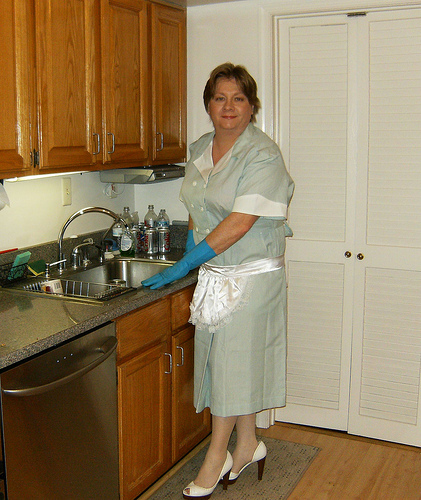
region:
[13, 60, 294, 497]
A woman standing next to a sink.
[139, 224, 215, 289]
Blue gloves on the woman's hands.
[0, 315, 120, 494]
Stainless steel dishwasher.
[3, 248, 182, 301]
A stainless steel sink.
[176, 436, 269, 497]
White shoes with brown heels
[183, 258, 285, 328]
White apron with a ruffle trim.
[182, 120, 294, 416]
Woman is wearing a blue and white dress.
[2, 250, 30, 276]
Green sponge on the edge of the sink.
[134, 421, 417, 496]
Brown wood flooring.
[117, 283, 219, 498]
Brown cupboards below the sink.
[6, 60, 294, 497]
a person in the kitchen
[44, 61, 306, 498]
a person in front of the sink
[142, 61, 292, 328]
a person wearing a blue gloves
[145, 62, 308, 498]
a person wearing high heels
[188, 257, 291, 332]
an apron the person is wearing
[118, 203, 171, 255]
bottles and soda cans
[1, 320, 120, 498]
a dishwasher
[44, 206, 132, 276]
a faucet on the sink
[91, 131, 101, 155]
a cabinet handle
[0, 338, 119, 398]
a handle of the dishwasher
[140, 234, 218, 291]
a blue glove on a woman's hand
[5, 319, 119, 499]
a metal dishwasher door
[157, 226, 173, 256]
a Diet Coke can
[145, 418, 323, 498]
a rug on the floor in front of a sink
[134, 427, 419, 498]
a light brown wood floor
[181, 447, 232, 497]
a white high heeled shoe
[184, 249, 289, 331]
a smal white apron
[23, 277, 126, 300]
a dish drainer in the sink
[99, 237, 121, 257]
a blue handled scrub brush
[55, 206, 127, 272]
a faucet on a sink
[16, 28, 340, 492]
woman standing in kitchen corner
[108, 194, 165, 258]
bottles in corner of counter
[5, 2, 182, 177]
wooden overhead storage cabinets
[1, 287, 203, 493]
cabinets next to steel dishwasher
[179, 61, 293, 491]
woman in a gray maid's uniform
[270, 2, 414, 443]
double white doors covered in slats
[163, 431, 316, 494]
high heeled shoes on beige mat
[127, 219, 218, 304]
blue rubber gloves resting on gray counter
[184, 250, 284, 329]
white satin apron with lace edging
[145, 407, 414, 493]
patterned mat on wooden floor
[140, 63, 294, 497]
A brown haired woman with blue gloves and high heels on.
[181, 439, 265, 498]
White dress shoes with brown heels.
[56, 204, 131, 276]
A silver faucet over a sink.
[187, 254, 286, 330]
A white satin apron with lace on the trim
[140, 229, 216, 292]
Blue latex gloves on a woman's hands.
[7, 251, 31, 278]
A light blue sponge by the sink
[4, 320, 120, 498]
A stainless steel dishwasher under the counter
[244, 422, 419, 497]
A wood floor.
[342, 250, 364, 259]
Two gold knobs on the white double doors.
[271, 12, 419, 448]
Two white double doors with gold knobs.